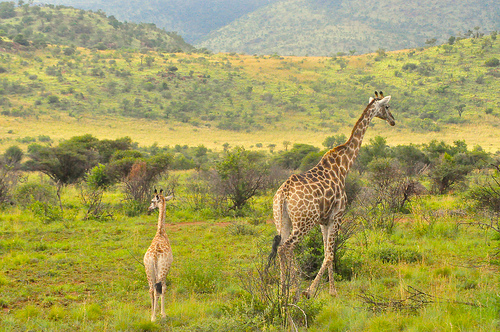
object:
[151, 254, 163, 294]
tail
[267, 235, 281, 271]
black hair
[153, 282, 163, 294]
black hair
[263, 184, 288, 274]
tail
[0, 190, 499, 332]
grass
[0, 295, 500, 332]
ground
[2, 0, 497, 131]
hills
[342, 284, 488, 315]
branch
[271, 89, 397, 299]
adult giraffe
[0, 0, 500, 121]
mountains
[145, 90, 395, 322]
two giraffes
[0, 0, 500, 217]
trees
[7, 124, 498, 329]
land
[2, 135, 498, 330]
vegetation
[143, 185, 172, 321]
giraffe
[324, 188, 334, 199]
spots